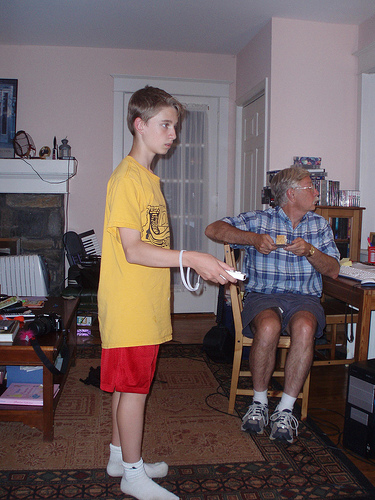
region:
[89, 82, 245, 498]
a boy stands in middle of a room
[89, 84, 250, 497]
boy wears a long yellow shirt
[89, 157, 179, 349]
yellow shirt has a black design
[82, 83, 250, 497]
boy is looking to the right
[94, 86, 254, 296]
boy holds a Wii control on right hand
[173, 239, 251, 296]
Wii control with gray strap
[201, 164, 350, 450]
an old man sits on a chair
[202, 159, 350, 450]
old man face to the right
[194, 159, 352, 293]
man holds a small dish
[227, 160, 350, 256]
old man has gray hair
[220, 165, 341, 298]
Man wearing a blue and white plaid shirt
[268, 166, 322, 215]
Older gentleman wearing spectacle glasses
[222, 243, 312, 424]
Wooden desk chair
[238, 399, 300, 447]
Blue and gray tennis shoes with laces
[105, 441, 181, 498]
White socks with small dark logo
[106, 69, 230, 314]
Front door with a sheer curtain panel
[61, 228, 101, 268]
Black instrumental keyboard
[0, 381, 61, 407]
Pink covered children's book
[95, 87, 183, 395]
Boy in bright top and red shorts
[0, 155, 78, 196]
Simple white fireplace mantel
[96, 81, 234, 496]
young boy standing in living room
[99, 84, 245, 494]
boy playing video game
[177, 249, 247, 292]
Wii video game controller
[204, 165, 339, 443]
man sitting in wooden chair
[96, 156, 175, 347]
a yellow printed t-shirt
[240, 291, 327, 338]
a pair of men's blue shorts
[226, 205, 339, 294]
a blue plaid shirt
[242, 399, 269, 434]
a grey tennis shoe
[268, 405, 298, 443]
a grey tennis shoe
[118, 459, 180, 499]
a white sock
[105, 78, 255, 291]
a boy holding a game controller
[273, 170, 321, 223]
a man wearing glasses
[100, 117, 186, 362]
a boy wearing a yellow shirt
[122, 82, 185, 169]
a boy with short hair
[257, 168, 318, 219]
a man with grey hair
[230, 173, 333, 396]
a man sitting in a chair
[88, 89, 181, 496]
a boy wearing red shorts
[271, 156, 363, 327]
a man holding a plate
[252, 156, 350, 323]
a man sitting at a table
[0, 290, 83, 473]
a wooden table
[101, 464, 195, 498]
a boy wearing white socks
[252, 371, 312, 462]
a man wearing tennis shoes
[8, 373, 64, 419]
a book laying on a table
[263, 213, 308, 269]
man holding a piece of cake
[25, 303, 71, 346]
a camera sitting on a table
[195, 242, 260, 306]
a boy holding a controler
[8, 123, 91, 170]
lots of items sitting on a shelf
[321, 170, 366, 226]
movies sitting on a shelf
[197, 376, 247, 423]
a black cord on the floor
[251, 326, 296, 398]
hair on a mans legs